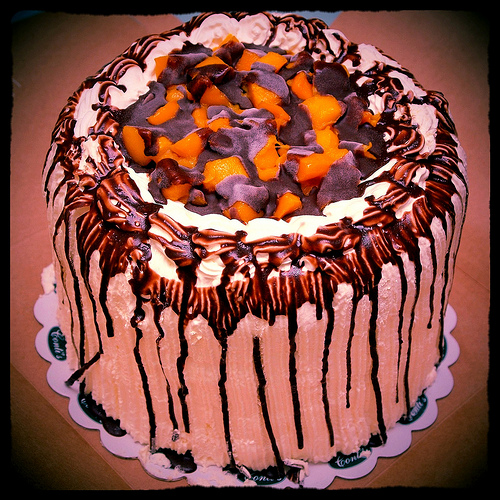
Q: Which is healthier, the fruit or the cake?
A: The fruit is healthier than the cake.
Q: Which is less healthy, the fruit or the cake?
A: The cake is less healthy than the fruit.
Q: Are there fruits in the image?
A: Yes, there is a fruit.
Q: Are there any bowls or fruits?
A: Yes, there is a fruit.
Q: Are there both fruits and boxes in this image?
A: No, there is a fruit but no boxes.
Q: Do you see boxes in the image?
A: No, there are no boxes.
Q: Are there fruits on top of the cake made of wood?
A: Yes, there is a fruit on top of the cake.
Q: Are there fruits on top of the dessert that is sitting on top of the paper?
A: Yes, there is a fruit on top of the cake.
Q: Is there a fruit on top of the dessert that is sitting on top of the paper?
A: Yes, there is a fruit on top of the cake.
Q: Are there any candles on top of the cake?
A: No, there is a fruit on top of the cake.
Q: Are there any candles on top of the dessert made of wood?
A: No, there is a fruit on top of the cake.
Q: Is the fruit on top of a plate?
A: No, the fruit is on top of the cake.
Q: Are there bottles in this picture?
A: No, there are no bottles.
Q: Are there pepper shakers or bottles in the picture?
A: No, there are no bottles or pepper shakers.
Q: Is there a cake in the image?
A: Yes, there is a cake.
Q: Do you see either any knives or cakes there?
A: Yes, there is a cake.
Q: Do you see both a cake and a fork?
A: No, there is a cake but no forks.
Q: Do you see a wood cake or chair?
A: Yes, there is a wood cake.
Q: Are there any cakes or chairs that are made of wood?
A: Yes, the cake is made of wood.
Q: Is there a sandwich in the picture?
A: No, there are no sandwiches.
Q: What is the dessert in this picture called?
A: The dessert is a cake.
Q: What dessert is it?
A: The dessert is a cake.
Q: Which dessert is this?
A: This is a cake.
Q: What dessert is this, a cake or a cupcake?
A: This is a cake.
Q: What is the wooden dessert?
A: The dessert is a cake.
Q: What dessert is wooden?
A: The dessert is a cake.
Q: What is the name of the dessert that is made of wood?
A: The dessert is a cake.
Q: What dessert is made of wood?
A: The dessert is a cake.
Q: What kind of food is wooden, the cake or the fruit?
A: The cake is wooden.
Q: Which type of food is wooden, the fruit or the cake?
A: The cake is wooden.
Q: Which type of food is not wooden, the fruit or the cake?
A: The fruit is not wooden.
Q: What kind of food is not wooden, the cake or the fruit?
A: The fruit is not wooden.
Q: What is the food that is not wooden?
A: The food is a fruit.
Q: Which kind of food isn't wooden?
A: The food is a fruit.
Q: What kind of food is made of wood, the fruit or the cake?
A: The cake is made of wood.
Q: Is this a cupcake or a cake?
A: This is a cake.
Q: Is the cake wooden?
A: Yes, the cake is wooden.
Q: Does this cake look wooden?
A: Yes, the cake is wooden.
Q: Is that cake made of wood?
A: Yes, the cake is made of wood.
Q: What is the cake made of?
A: The cake is made of wood.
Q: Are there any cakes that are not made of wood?
A: No, there is a cake but it is made of wood.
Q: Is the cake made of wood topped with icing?
A: Yes, the cake is topped with icing.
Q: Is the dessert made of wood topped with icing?
A: Yes, the cake is topped with icing.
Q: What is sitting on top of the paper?
A: The cake is sitting on top of the paper.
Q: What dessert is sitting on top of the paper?
A: The dessert is a cake.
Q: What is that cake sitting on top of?
A: The cake is sitting on top of the paper.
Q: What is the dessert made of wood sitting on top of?
A: The cake is sitting on top of the paper.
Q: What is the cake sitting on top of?
A: The cake is sitting on top of the paper.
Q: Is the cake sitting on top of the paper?
A: Yes, the cake is sitting on top of the paper.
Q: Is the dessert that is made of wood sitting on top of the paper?
A: Yes, the cake is sitting on top of the paper.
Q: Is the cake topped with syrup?
A: Yes, the cake is topped with syrup.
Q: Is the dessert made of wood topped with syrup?
A: Yes, the cake is topped with syrup.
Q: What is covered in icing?
A: The cake is covered in icing.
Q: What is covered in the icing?
A: The cake is covered in icing.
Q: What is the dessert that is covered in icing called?
A: The dessert is a cake.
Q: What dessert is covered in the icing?
A: The dessert is a cake.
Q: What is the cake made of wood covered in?
A: The cake is covered in icing.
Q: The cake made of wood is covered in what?
A: The cake is covered in icing.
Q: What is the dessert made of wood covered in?
A: The cake is covered in icing.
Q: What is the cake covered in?
A: The cake is covered in icing.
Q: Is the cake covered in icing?
A: Yes, the cake is covered in icing.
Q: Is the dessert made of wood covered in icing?
A: Yes, the cake is covered in icing.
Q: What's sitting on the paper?
A: The cake is sitting on the paper.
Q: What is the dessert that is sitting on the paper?
A: The dessert is a cake.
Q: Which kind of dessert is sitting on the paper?
A: The dessert is a cake.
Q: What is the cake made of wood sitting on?
A: The cake is sitting on the paper.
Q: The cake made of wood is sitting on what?
A: The cake is sitting on the paper.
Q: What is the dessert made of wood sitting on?
A: The cake is sitting on the paper.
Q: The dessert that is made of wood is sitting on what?
A: The cake is sitting on the paper.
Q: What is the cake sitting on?
A: The cake is sitting on the paper.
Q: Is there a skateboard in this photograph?
A: No, there are no skateboards.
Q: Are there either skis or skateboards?
A: No, there are no skateboards or skis.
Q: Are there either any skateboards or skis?
A: No, there are no skateboards or skis.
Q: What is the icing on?
A: The icing is on the cake.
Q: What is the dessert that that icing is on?
A: The dessert is a cake.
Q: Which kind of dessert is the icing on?
A: The icing is on the cake.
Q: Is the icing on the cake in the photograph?
A: Yes, the icing is on the cake.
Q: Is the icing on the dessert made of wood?
A: Yes, the icing is on the cake.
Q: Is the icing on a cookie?
A: No, the icing is on the cake.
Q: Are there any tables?
A: Yes, there is a table.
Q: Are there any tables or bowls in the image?
A: Yes, there is a table.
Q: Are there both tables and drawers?
A: No, there is a table but no drawers.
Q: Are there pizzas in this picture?
A: No, there are no pizzas.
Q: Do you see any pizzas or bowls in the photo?
A: No, there are no pizzas or bowls.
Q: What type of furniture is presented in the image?
A: The furniture is a table.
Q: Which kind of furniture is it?
A: The piece of furniture is a table.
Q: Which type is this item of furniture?
A: This is a table.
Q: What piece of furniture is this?
A: This is a table.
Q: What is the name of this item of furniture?
A: This is a table.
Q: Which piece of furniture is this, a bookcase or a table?
A: This is a table.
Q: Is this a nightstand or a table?
A: This is a table.